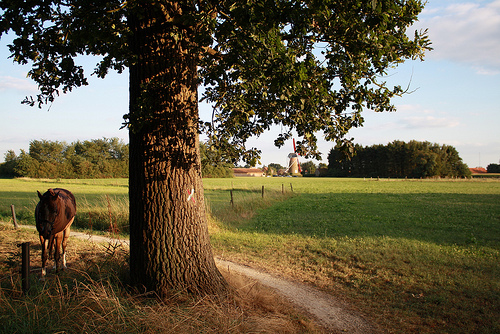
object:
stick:
[262, 186, 264, 198]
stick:
[281, 183, 284, 193]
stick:
[289, 182, 294, 192]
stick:
[229, 191, 235, 207]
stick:
[231, 180, 234, 189]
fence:
[9, 182, 296, 227]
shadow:
[128, 53, 202, 186]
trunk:
[124, 2, 232, 300]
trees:
[316, 136, 476, 179]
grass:
[0, 260, 290, 334]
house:
[234, 168, 265, 177]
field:
[6, 168, 499, 328]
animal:
[34, 187, 76, 277]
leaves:
[0, 0, 436, 156]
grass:
[247, 176, 500, 292]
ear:
[36, 190, 43, 200]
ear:
[53, 190, 61, 201]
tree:
[0, 0, 432, 304]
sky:
[0, 0, 497, 154]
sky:
[0, 0, 500, 137]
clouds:
[1, 37, 500, 114]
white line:
[187, 185, 195, 202]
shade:
[210, 188, 499, 250]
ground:
[0, 184, 500, 334]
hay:
[338, 267, 462, 313]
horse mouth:
[35, 219, 55, 240]